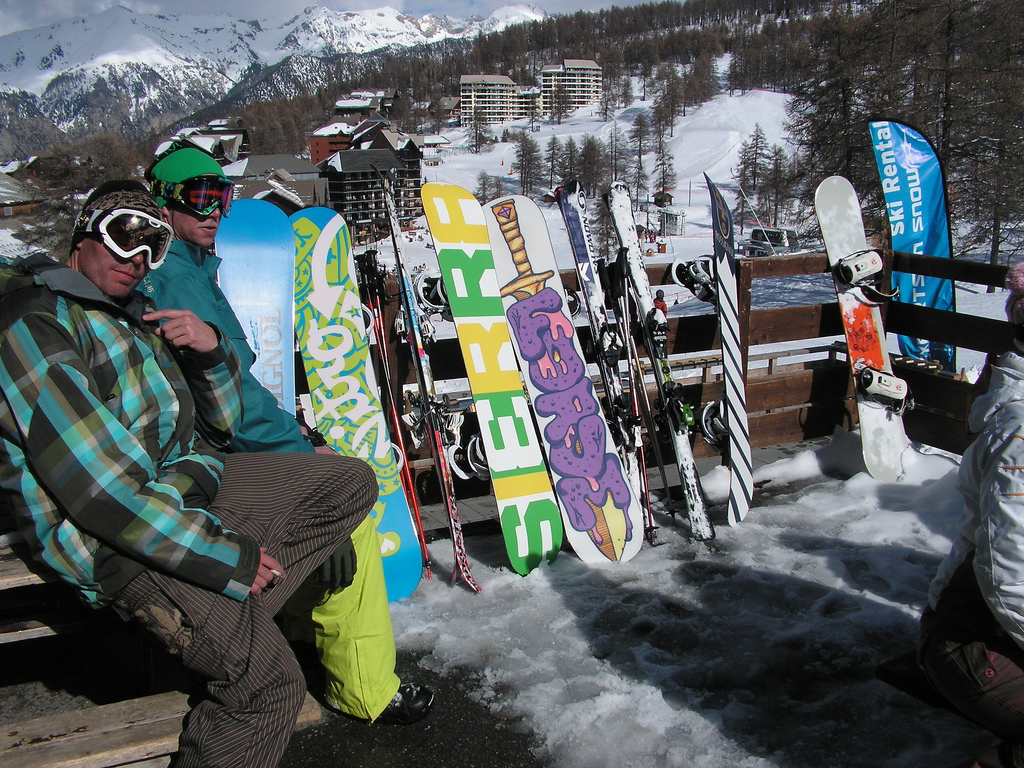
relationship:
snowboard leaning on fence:
[289, 201, 416, 604] [0, 250, 858, 643]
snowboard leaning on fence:
[418, 183, 568, 585] [0, 250, 858, 643]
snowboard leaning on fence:
[487, 187, 647, 570] [4, 243, 880, 601]